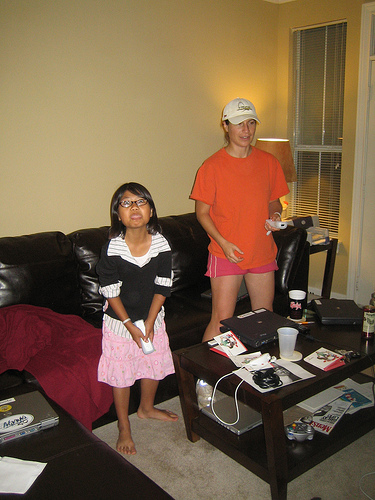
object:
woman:
[188, 98, 289, 343]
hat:
[222, 96, 262, 123]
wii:
[266, 217, 288, 229]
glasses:
[114, 196, 147, 209]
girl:
[94, 180, 178, 452]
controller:
[133, 318, 153, 354]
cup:
[276, 325, 298, 358]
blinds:
[289, 23, 346, 151]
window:
[283, 20, 343, 243]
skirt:
[96, 319, 174, 388]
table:
[171, 292, 375, 498]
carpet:
[90, 356, 375, 498]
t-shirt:
[188, 146, 289, 271]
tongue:
[129, 212, 141, 220]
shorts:
[206, 252, 279, 277]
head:
[222, 97, 261, 147]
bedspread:
[0, 303, 115, 428]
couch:
[0, 222, 79, 394]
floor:
[93, 352, 374, 499]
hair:
[106, 180, 162, 242]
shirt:
[94, 231, 174, 340]